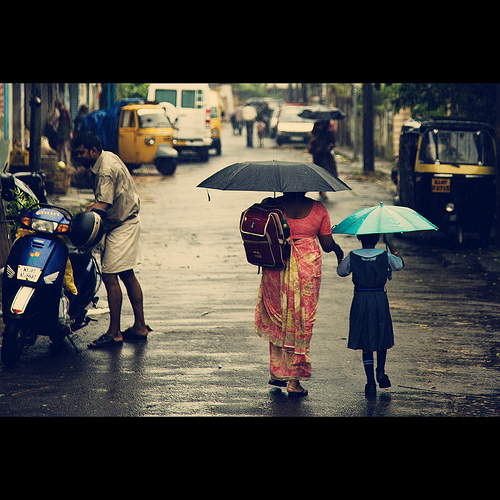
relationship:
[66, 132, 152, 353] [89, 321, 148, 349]
man wears sandals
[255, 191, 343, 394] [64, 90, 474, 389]
person walking in rain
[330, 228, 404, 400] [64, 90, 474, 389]
girl walking in rain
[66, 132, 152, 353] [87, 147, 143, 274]
man wearing outfit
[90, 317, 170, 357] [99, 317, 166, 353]
black sandals on feet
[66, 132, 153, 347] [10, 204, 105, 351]
man standing next to scooter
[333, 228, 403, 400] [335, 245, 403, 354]
girl wearing uniform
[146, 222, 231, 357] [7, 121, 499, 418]
rain on road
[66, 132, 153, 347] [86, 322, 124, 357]
man wearing black sandals